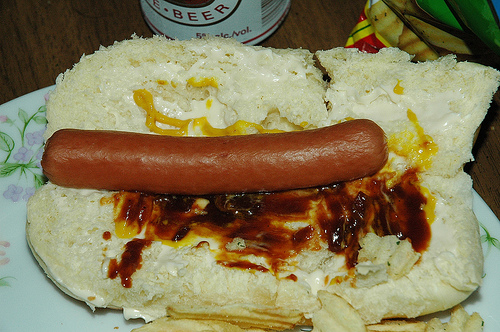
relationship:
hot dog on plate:
[40, 118, 388, 195] [4, 218, 481, 330]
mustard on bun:
[119, 75, 456, 271] [29, 37, 492, 317]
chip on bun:
[352, 228, 425, 285] [29, 37, 492, 317]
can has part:
[140, 0, 322, 58] [254, 26, 268, 40]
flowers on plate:
[13, 117, 31, 161] [5, 273, 44, 322]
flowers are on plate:
[1, 105, 57, 199] [3, 95, 45, 201]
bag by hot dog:
[342, 2, 479, 69] [32, 41, 494, 316]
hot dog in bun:
[40, 117, 392, 204] [29, 37, 492, 317]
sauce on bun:
[108, 170, 433, 285] [29, 37, 492, 317]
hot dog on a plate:
[40, 118, 388, 195] [22, 15, 493, 310]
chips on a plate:
[282, 290, 483, 330] [22, 15, 493, 310]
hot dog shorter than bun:
[40, 118, 388, 195] [29, 37, 492, 317]